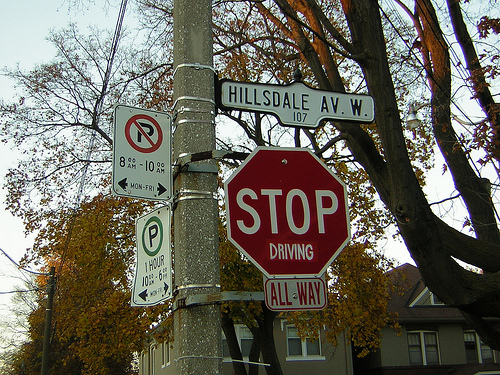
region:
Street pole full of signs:
[111, 2, 374, 314]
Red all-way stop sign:
[223, 146, 354, 312]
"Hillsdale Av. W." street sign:
[217, 75, 374, 125]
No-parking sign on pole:
[113, 103, 174, 202]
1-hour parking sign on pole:
[130, 208, 174, 306]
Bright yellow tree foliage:
[55, 218, 130, 362]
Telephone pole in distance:
[40, 267, 57, 364]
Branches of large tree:
[280, 1, 499, 341]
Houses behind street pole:
[227, 267, 499, 369]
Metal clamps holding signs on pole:
[170, 63, 218, 127]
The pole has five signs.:
[80, 32, 394, 313]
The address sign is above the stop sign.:
[212, 73, 385, 309]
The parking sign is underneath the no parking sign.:
[100, 95, 181, 310]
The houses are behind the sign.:
[184, 278, 494, 372]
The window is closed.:
[397, 323, 449, 368]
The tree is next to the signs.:
[208, 2, 497, 313]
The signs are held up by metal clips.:
[169, 38, 231, 321]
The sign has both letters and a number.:
[217, 75, 379, 135]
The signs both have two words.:
[222, 142, 349, 321]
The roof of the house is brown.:
[374, 253, 469, 333]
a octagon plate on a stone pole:
[224, 128, 358, 281]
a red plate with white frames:
[215, 133, 355, 278]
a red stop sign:
[224, 138, 362, 273]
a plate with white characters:
[220, 141, 358, 279]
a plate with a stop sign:
[217, 133, 351, 280]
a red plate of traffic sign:
[212, 130, 366, 283]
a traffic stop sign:
[210, 143, 356, 312]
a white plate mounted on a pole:
[124, 203, 191, 313]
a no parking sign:
[100, 80, 182, 214]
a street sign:
[190, 64, 390, 144]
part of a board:
[278, 260, 294, 293]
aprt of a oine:
[188, 276, 211, 308]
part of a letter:
[278, 198, 294, 233]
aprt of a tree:
[346, 294, 369, 344]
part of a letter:
[299, 242, 327, 289]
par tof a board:
[270, 246, 307, 316]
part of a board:
[275, 214, 307, 259]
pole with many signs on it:
[173, 1, 218, 373]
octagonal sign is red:
[225, 146, 349, 279]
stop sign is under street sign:
[226, 146, 351, 278]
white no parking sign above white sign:
[112, 102, 171, 200]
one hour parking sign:
[131, 207, 172, 307]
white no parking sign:
[113, 103, 173, 199]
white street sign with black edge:
[223, 78, 373, 128]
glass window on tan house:
[287, 325, 301, 355]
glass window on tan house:
[305, 324, 321, 354]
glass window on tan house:
[238, 326, 254, 357]